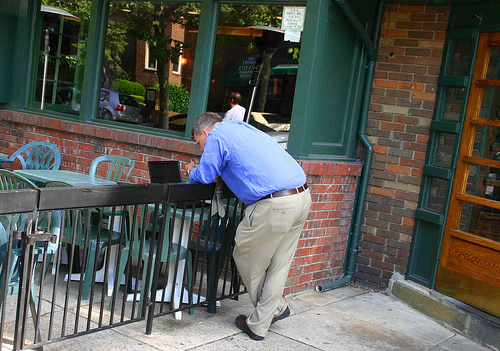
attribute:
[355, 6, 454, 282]
wall — red, brick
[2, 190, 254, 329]
fence — black, metal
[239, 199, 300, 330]
khaki pants — tan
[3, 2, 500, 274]
building — brick, green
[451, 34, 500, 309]
door — wooden, wood, gold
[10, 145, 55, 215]
chairs — green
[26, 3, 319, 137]
glass — large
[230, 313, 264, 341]
shoes — brown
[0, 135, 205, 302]
furniture — green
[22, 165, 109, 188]
table — plastic, green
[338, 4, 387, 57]
gutter — green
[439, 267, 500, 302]
kick plate — brass